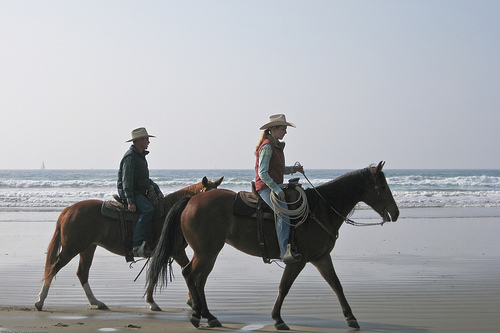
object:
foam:
[0, 174, 500, 212]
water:
[2, 168, 499, 210]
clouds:
[0, 0, 499, 169]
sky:
[0, 0, 499, 170]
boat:
[38, 160, 54, 177]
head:
[133, 127, 151, 149]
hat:
[259, 113, 296, 130]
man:
[116, 127, 164, 256]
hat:
[125, 127, 156, 143]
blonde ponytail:
[254, 128, 270, 155]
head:
[263, 114, 289, 140]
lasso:
[270, 184, 310, 227]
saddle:
[231, 177, 305, 265]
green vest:
[116, 145, 151, 198]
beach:
[0, 212, 500, 333]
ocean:
[1, 167, 500, 213]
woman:
[254, 113, 305, 260]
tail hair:
[144, 195, 189, 302]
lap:
[269, 182, 310, 227]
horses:
[144, 160, 401, 331]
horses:
[34, 177, 225, 312]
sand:
[0, 235, 499, 332]